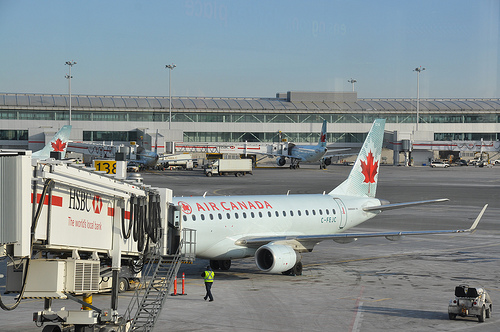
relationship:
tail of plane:
[343, 120, 388, 212] [170, 126, 400, 280]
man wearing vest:
[199, 256, 216, 297] [201, 266, 219, 283]